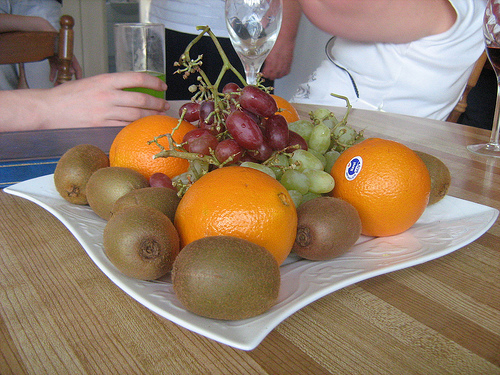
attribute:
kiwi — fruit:
[53, 146, 453, 324]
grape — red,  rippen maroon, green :
[169, 79, 308, 177]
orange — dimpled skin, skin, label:
[115, 85, 431, 275]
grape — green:
[183, 103, 363, 204]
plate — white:
[5, 133, 499, 354]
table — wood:
[3, 85, 499, 371]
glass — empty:
[226, 0, 286, 102]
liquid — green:
[120, 70, 167, 99]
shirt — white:
[296, 4, 488, 123]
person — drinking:
[1, 5, 164, 143]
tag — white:
[345, 156, 364, 179]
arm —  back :
[5, 15, 168, 139]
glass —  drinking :
[116, 20, 176, 116]